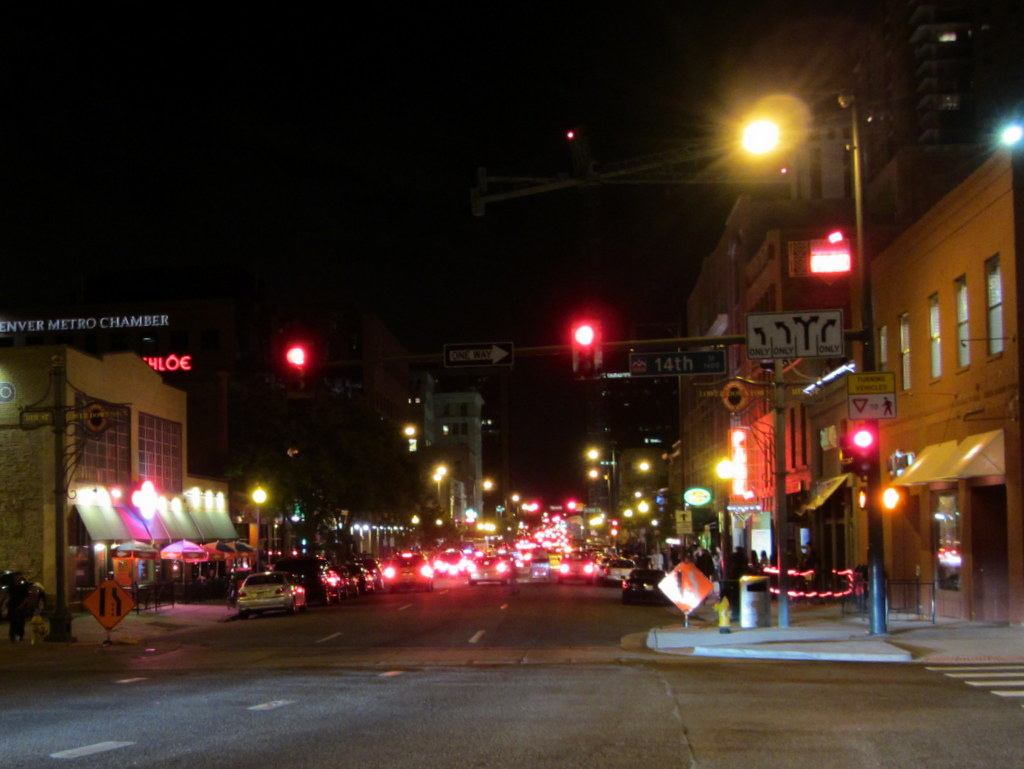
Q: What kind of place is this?
A: It is a road.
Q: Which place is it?
A: It is a road.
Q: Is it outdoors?
A: Yes, it is outdoors.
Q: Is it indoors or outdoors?
A: It is outdoors.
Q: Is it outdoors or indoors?
A: It is outdoors.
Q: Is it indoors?
A: No, it is outdoors.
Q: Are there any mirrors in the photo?
A: No, there are no mirrors.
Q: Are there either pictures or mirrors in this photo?
A: No, there are no mirrors or pictures.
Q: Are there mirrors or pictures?
A: No, there are no mirrors or pictures.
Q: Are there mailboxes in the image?
A: No, there are no mailboxes.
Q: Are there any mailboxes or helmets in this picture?
A: No, there are no mailboxes or helmets.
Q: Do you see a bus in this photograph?
A: No, there are no buses.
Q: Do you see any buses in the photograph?
A: No, there are no buses.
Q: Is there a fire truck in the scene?
A: No, there are no fire trucks.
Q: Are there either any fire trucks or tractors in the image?
A: No, there are no fire trucks or tractors.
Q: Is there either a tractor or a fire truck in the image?
A: No, there are no fire trucks or tractors.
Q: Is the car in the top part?
A: No, the car is in the bottom of the image.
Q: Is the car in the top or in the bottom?
A: The car is in the bottom of the image.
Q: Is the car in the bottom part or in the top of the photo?
A: The car is in the bottom of the image.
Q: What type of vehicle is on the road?
A: The vehicle is a car.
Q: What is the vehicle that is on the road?
A: The vehicle is a car.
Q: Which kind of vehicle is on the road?
A: The vehicle is a car.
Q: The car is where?
A: The car is on the road.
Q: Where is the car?
A: The car is on the road.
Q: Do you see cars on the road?
A: Yes, there is a car on the road.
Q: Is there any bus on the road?
A: No, there is a car on the road.